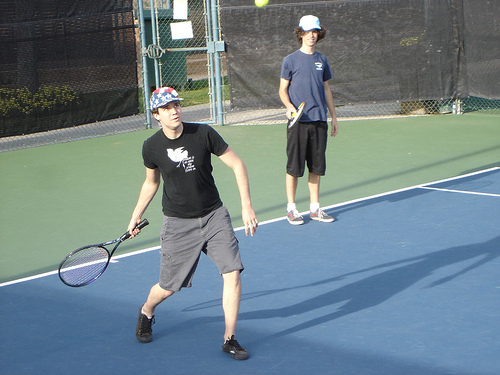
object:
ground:
[0, 123, 500, 374]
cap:
[146, 87, 183, 109]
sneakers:
[221, 334, 250, 361]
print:
[167, 144, 198, 174]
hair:
[292, 25, 324, 40]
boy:
[128, 86, 259, 361]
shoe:
[222, 334, 249, 361]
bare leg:
[141, 279, 174, 318]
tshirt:
[143, 122, 229, 224]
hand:
[328, 119, 340, 138]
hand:
[285, 104, 299, 120]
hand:
[127, 217, 143, 238]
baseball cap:
[296, 15, 323, 32]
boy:
[278, 14, 336, 227]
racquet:
[282, 102, 311, 127]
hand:
[239, 207, 258, 238]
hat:
[149, 86, 185, 110]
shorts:
[158, 205, 243, 294]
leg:
[223, 268, 243, 340]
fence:
[136, 0, 226, 130]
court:
[0, 111, 500, 374]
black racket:
[57, 219, 152, 288]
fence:
[0, 30, 142, 137]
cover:
[0, 0, 147, 153]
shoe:
[135, 310, 156, 344]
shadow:
[156, 236, 498, 350]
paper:
[167, 20, 195, 40]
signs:
[169, 0, 194, 41]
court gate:
[0, 2, 281, 152]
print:
[311, 59, 326, 73]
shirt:
[280, 46, 331, 125]